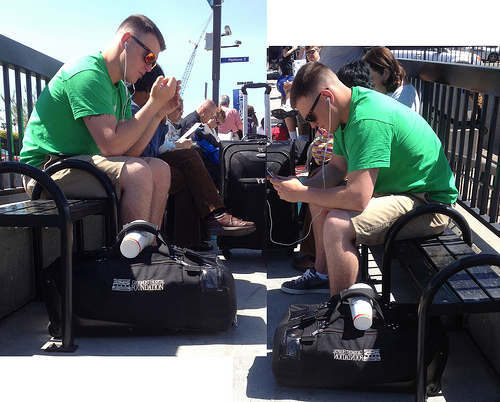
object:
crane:
[170, 10, 212, 100]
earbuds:
[120, 38, 132, 120]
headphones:
[266, 94, 333, 248]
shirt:
[322, 86, 461, 206]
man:
[268, 59, 458, 311]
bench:
[337, 57, 500, 400]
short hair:
[291, 58, 331, 108]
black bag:
[271, 288, 453, 397]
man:
[19, 11, 182, 249]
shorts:
[340, 192, 451, 250]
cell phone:
[267, 169, 283, 184]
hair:
[114, 14, 167, 55]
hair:
[361, 44, 406, 95]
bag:
[46, 219, 238, 338]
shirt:
[17, 50, 137, 178]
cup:
[118, 219, 155, 259]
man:
[179, 99, 216, 138]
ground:
[0, 203, 500, 401]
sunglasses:
[134, 36, 162, 72]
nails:
[157, 76, 165, 81]